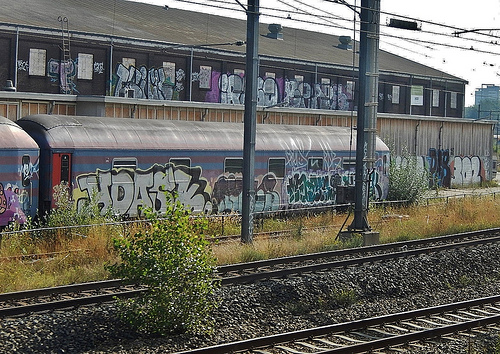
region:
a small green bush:
[117, 200, 219, 335]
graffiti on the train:
[73, 165, 215, 219]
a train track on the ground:
[185, 286, 499, 348]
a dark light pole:
[344, 0, 388, 239]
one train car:
[15, 105, 395, 209]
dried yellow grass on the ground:
[0, 185, 497, 257]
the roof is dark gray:
[0, 0, 463, 83]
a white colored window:
[24, 47, 49, 79]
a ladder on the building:
[56, 14, 78, 95]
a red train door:
[51, 151, 71, 219]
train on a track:
[8, 110, 396, 217]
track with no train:
[398, 298, 490, 331]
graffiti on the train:
[72, 162, 206, 211]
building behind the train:
[1, 80, 499, 185]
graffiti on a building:
[38, 40, 368, 110]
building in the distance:
[476, 73, 494, 105]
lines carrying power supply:
[325, 4, 496, 65]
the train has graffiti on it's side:
[2, 139, 393, 237]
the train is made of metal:
[2, 112, 389, 233]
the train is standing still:
[0, 117, 387, 237]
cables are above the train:
[168, 0, 498, 81]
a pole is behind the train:
[241, 2, 258, 244]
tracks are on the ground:
[3, 230, 495, 352]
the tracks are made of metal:
[4, 229, 494, 351]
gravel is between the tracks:
[3, 237, 499, 351]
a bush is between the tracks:
[111, 202, 216, 339]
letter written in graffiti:
[108, 167, 132, 216]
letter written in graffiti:
[130, 171, 157, 215]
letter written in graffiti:
[148, 165, 176, 212]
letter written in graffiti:
[171, 165, 211, 215]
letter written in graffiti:
[111, 63, 126, 97]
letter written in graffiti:
[129, 64, 147, 98]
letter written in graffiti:
[150, 68, 165, 98]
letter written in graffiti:
[217, 73, 240, 103]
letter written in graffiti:
[263, 77, 278, 105]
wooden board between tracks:
[276, 343, 295, 353]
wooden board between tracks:
[295, 338, 327, 352]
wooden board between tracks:
[313, 333, 341, 348]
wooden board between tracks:
[333, 331, 361, 342]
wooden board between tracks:
[352, 328, 378, 341]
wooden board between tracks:
[368, 323, 392, 338]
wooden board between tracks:
[386, 320, 415, 332]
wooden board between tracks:
[418, 316, 440, 326]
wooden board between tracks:
[443, 310, 472, 323]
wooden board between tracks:
[471, 305, 493, 315]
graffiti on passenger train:
[82, 149, 376, 214]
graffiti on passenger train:
[38, 146, 205, 215]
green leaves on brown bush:
[143, 255, 190, 285]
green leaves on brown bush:
[158, 209, 189, 226]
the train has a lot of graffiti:
[1, 115, 389, 218]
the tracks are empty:
[1, 227, 498, 352]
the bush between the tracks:
[1, 175, 498, 350]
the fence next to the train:
[0, 113, 499, 293]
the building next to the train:
[1, 0, 499, 230]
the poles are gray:
[238, 0, 383, 245]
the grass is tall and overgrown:
[2, 187, 499, 293]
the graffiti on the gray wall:
[1, 89, 498, 190]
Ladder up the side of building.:
[55, 14, 77, 94]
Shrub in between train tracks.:
[107, 182, 214, 337]